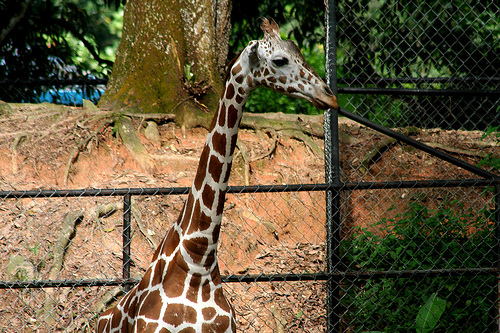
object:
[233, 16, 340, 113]
giraffe's head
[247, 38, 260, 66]
ear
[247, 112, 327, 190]
roots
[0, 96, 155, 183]
roots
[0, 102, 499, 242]
soil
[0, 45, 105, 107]
bluecar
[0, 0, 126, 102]
leaves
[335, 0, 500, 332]
wall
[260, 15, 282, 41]
horns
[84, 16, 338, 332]
giraffe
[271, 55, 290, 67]
eye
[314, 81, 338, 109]
nose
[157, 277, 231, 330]
spots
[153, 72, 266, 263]
giraffe neck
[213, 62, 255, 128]
brown squares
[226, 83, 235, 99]
shape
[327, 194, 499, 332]
plants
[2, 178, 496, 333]
poles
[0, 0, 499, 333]
fence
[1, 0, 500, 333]
fencing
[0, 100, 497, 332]
hill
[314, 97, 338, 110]
mouth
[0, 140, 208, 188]
dirt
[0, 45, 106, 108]
pool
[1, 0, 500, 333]
wires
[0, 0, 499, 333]
fenced area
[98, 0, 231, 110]
tree trunk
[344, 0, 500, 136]
leaves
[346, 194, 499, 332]
leaves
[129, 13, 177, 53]
spots